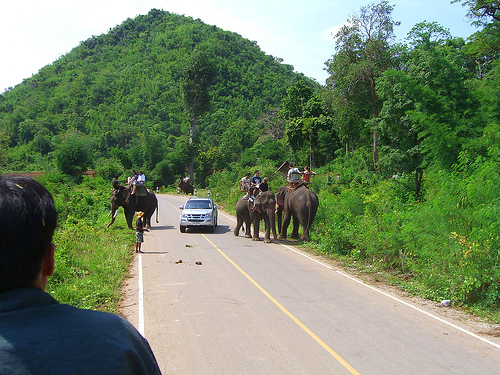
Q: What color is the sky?
A: Blue.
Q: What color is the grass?
A: Green.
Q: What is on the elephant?
A: People.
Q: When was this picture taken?
A: During the day.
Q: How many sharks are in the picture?
A: Zero.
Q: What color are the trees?
A: Green.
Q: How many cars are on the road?
A: One.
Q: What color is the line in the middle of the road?
A: Yellow.